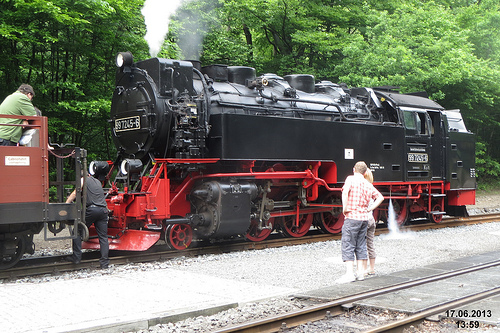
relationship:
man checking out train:
[63, 168, 113, 274] [0, 51, 478, 270]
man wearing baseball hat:
[63, 168, 113, 274] [76, 167, 94, 178]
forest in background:
[0, 0, 499, 192] [0, 1, 500, 203]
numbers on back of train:
[113, 115, 144, 135] [0, 51, 478, 270]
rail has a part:
[367, 285, 500, 332] [355, 312, 425, 331]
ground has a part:
[3, 196, 500, 329] [293, 245, 500, 323]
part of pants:
[341, 221, 361, 260] [341, 219, 373, 261]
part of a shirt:
[369, 182, 382, 202] [341, 174, 380, 223]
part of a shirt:
[21, 99, 40, 117] [0, 92, 41, 148]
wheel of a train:
[167, 221, 198, 253] [0, 51, 478, 270]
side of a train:
[150, 58, 482, 254] [0, 51, 478, 270]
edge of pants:
[344, 251, 360, 265] [341, 219, 373, 261]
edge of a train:
[165, 160, 483, 253] [0, 51, 478, 270]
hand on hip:
[364, 204, 371, 212] [360, 205, 376, 226]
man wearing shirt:
[0, 84, 45, 147] [0, 92, 41, 148]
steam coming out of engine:
[140, 1, 222, 63] [154, 55, 379, 251]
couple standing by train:
[343, 159, 382, 285] [0, 51, 478, 270]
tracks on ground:
[220, 257, 500, 332] [3, 196, 500, 329]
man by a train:
[63, 168, 113, 274] [0, 51, 478, 270]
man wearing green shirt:
[0, 84, 45, 147] [0, 92, 41, 148]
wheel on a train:
[280, 191, 318, 237] [0, 51, 478, 270]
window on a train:
[398, 105, 433, 136] [0, 51, 478, 270]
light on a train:
[115, 50, 127, 69] [0, 51, 478, 270]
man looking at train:
[63, 168, 113, 274] [0, 51, 478, 270]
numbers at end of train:
[113, 115, 144, 135] [103, 49, 170, 165]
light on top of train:
[115, 50, 127, 69] [0, 51, 478, 270]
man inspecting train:
[63, 168, 113, 274] [0, 51, 478, 270]